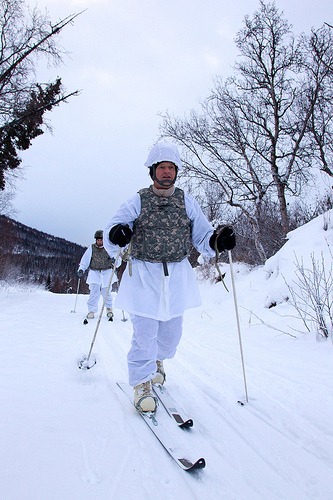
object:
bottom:
[77, 351, 100, 372]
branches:
[280, 247, 333, 342]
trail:
[219, 421, 303, 499]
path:
[86, 335, 265, 475]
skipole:
[225, 252, 258, 408]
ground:
[265, 379, 312, 470]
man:
[103, 135, 236, 418]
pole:
[87, 251, 118, 368]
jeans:
[127, 264, 185, 387]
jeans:
[87, 269, 117, 319]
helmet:
[93, 228, 103, 238]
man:
[76, 229, 120, 319]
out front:
[50, 151, 284, 391]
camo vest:
[129, 187, 192, 264]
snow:
[0, 292, 332, 498]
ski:
[116, 379, 205, 472]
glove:
[109, 222, 132, 246]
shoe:
[131, 381, 156, 414]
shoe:
[149, 360, 165, 386]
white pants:
[114, 254, 204, 322]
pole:
[225, 245, 251, 403]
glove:
[208, 224, 237, 250]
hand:
[208, 225, 236, 253]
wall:
[183, 87, 212, 113]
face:
[153, 161, 179, 185]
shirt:
[103, 186, 218, 323]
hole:
[267, 299, 277, 309]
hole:
[268, 271, 273, 274]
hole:
[283, 295, 289, 302]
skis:
[115, 376, 209, 474]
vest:
[88, 244, 112, 268]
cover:
[144, 141, 184, 170]